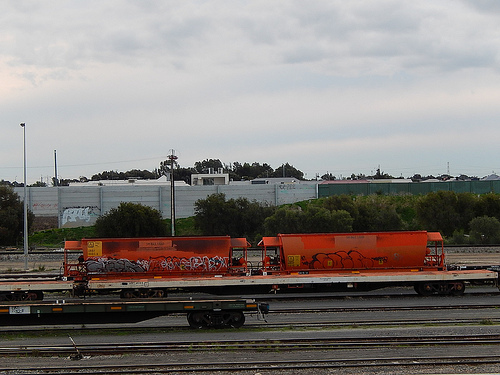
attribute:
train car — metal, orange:
[257, 230, 448, 275]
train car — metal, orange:
[60, 235, 253, 281]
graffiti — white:
[86, 256, 229, 274]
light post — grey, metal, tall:
[19, 121, 29, 270]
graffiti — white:
[61, 205, 92, 223]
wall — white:
[14, 179, 500, 233]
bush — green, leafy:
[95, 199, 169, 237]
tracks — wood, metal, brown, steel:
[0, 242, 498, 255]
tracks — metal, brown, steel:
[0, 271, 499, 373]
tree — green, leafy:
[1, 183, 36, 243]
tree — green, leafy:
[193, 192, 275, 232]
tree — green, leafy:
[262, 206, 353, 234]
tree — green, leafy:
[316, 193, 361, 231]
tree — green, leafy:
[416, 191, 499, 239]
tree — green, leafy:
[383, 192, 425, 230]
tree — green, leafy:
[355, 194, 387, 233]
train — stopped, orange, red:
[52, 230, 446, 288]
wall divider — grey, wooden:
[29, 186, 33, 213]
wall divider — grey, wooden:
[57, 188, 63, 229]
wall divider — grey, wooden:
[99, 186, 103, 218]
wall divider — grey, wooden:
[158, 185, 161, 213]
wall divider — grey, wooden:
[216, 183, 221, 192]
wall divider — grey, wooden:
[275, 183, 278, 205]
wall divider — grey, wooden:
[315, 181, 320, 196]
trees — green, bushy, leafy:
[193, 191, 499, 245]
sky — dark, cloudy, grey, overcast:
[2, 2, 498, 186]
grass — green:
[2, 317, 499, 338]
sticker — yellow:
[86, 239, 103, 258]